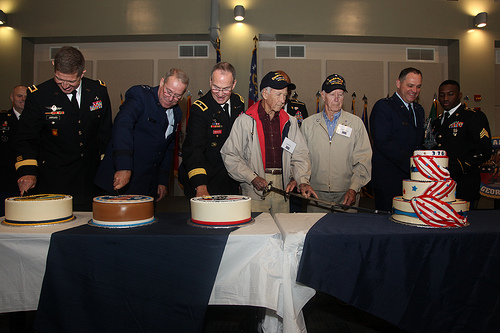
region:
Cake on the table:
[390, 146, 475, 230]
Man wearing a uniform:
[427, 76, 494, 208]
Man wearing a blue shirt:
[294, 72, 372, 212]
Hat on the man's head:
[321, 68, 348, 93]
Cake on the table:
[176, 180, 257, 226]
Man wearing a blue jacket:
[102, 55, 182, 190]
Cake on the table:
[82, 182, 157, 230]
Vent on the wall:
[396, 32, 442, 67]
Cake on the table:
[1, 180, 78, 236]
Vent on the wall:
[171, 36, 218, 64]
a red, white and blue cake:
[385, 145, 475, 231]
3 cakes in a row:
[3, 187, 254, 234]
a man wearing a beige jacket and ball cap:
[301, 73, 372, 211]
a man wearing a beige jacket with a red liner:
[234, 68, 314, 205]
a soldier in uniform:
[6, 43, 113, 193]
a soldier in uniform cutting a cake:
[4, 41, 113, 229]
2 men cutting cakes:
[5, 42, 191, 234]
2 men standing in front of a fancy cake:
[371, 64, 494, 234]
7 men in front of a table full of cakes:
[20, 43, 494, 318]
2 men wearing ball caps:
[244, 67, 361, 131]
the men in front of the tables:
[14, 44, 491, 214]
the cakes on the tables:
[2, 148, 468, 226]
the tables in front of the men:
[1, 210, 496, 331]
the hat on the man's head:
[320, 73, 346, 95]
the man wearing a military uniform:
[424, 79, 493, 204]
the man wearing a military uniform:
[14, 45, 110, 210]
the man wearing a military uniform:
[177, 60, 243, 200]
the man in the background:
[0, 84, 26, 198]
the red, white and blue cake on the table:
[389, 148, 471, 227]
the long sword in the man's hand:
[251, 172, 394, 216]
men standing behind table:
[96, 40, 385, 255]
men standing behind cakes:
[58, 73, 493, 238]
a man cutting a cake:
[219, 79, 496, 273]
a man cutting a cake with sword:
[222, 58, 479, 258]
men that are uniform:
[35, 41, 451, 321]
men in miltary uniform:
[25, 15, 493, 257]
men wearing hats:
[258, 77, 418, 229]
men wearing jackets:
[228, 50, 345, 184]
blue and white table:
[82, 146, 319, 328]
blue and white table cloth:
[151, 211, 336, 330]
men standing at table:
[15, 45, 496, 207]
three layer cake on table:
[401, 151, 468, 245]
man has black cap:
[328, 68, 355, 103]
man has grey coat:
[292, 117, 364, 181]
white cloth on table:
[214, 204, 336, 325]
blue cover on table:
[288, 218, 498, 326]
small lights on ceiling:
[224, 11, 258, 32]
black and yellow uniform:
[17, 74, 111, 189]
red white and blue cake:
[408, 155, 449, 237]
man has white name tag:
[328, 121, 353, 151]